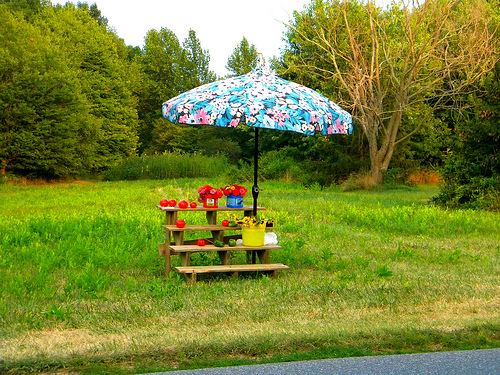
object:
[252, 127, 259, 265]
pole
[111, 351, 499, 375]
street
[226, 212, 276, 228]
flowers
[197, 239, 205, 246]
fruit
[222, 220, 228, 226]
fruit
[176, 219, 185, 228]
fruit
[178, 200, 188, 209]
fruit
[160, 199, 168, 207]
fruit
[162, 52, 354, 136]
umbella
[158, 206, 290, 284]
stand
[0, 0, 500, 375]
park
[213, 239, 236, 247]
cucumbers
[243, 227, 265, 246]
bucket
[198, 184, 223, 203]
red flowers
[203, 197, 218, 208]
red bucket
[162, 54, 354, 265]
umbrella stand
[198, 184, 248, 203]
flowers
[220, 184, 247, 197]
flower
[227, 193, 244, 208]
bucket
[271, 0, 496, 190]
tree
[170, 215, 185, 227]
tomatoe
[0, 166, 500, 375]
field